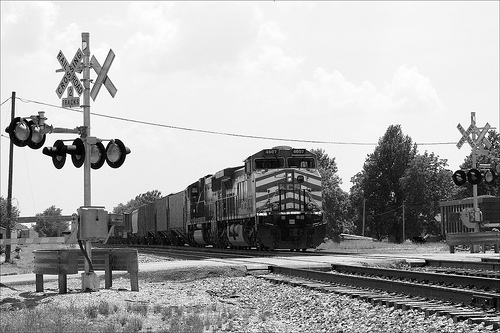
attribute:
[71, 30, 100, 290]
pole — large, metal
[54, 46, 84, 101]
sign — large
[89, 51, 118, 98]
sign — large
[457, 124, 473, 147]
sign — large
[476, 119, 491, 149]
sign — large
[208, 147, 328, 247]
engine — large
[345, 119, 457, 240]
tree — large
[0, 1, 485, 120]
sky — white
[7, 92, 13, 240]
pole — tall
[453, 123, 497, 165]
crossingsign — large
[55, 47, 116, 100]
crossingsign — large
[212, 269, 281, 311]
rocks — small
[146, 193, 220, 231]
train carts — large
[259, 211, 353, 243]
guard — black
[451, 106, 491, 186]
sign — large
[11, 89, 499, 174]
wire — long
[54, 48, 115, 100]
sign — large